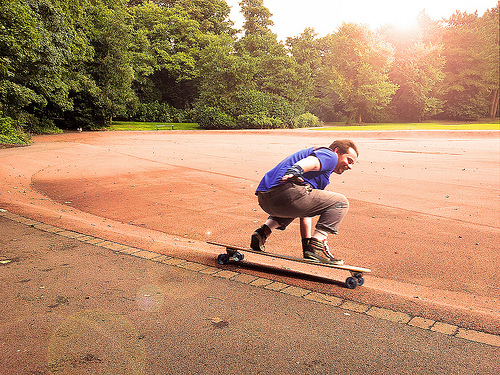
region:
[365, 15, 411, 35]
the sun in the sky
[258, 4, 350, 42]
the sky behind the trees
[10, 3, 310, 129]
green tall trees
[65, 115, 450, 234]
the sidewalk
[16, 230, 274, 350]
the black pavement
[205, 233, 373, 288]
a skateboard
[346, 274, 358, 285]
the wheel of the skateboard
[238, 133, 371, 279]
a man riding a skateboard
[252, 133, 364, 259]
a man in a blue shirt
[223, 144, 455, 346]
a man skateboarding down the street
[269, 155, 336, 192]
Man with blue shirt on top of the road.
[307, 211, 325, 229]
Man with blue shirt on top of the road.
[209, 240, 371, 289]
a skate board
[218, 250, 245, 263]
the wheels of a skate board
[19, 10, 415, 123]
a forest of green trees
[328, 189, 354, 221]
the knee of a man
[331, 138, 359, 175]
the head of a man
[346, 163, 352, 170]
the nose of a man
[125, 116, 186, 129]
the green lawn next to the forest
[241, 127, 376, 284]
a man on a skate board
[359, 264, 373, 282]
the nose of a skate board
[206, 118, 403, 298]
person skateboarding on sidewalk curb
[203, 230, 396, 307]
four wheel skateboard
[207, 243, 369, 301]
wheels on bottom of skateboard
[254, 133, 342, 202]
purple short sleeve shirt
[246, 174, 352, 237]
tan pants with rolled up cuffs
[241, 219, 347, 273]
black and red sneakers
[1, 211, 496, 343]
line of bricks bordering sidewalk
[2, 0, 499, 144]
line of trees and brush on edge of road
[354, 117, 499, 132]
section of green grass in front of trees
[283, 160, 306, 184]
black fingerless gloves